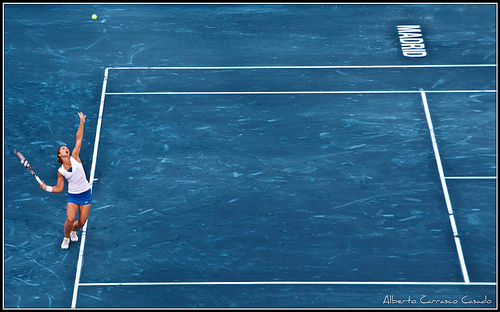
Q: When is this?
A: Daytime.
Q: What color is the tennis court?
A: Blue.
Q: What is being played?
A: Tennis.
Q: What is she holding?
A: Tennis racket.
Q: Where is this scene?
A: Tennis court.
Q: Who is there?
A: Tennis player.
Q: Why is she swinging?
A: For the ball.